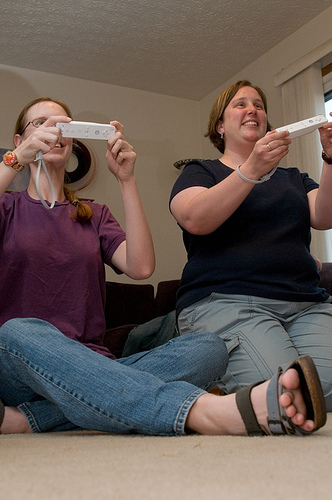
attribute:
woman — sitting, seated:
[3, 97, 330, 432]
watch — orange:
[5, 141, 27, 184]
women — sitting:
[10, 63, 323, 381]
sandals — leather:
[186, 335, 309, 453]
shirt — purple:
[13, 204, 134, 321]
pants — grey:
[200, 273, 323, 375]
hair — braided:
[14, 101, 97, 233]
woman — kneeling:
[187, 94, 326, 404]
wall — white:
[114, 91, 170, 244]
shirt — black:
[170, 163, 320, 302]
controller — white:
[51, 116, 114, 150]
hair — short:
[185, 76, 244, 152]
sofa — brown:
[115, 268, 175, 321]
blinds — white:
[278, 81, 325, 177]